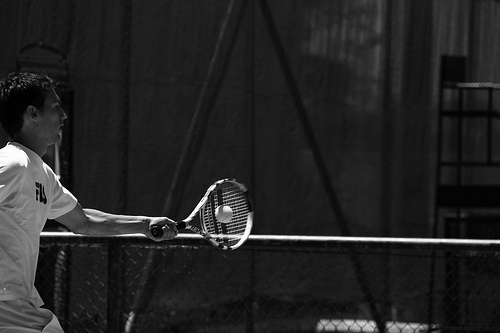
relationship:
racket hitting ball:
[151, 178, 256, 251] [211, 200, 233, 226]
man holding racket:
[0, 71, 180, 332] [151, 178, 256, 251]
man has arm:
[0, 71, 180, 332] [45, 162, 178, 242]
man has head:
[0, 71, 180, 332] [1, 70, 70, 150]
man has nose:
[0, 71, 180, 332] [60, 106, 68, 122]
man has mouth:
[0, 71, 180, 332] [56, 122, 67, 136]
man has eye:
[0, 71, 180, 332] [51, 101, 61, 109]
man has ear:
[0, 71, 180, 332] [23, 102, 41, 124]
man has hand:
[0, 71, 180, 332] [144, 216, 179, 243]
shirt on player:
[1, 141, 79, 332] [1, 72, 178, 332]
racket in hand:
[151, 178, 256, 251] [144, 216, 179, 243]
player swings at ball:
[1, 72, 178, 332] [211, 200, 233, 226]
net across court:
[37, 231, 498, 332] [1, 63, 499, 332]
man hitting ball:
[0, 71, 180, 332] [211, 200, 233, 226]